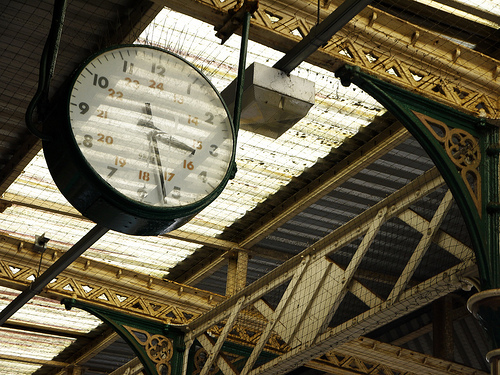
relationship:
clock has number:
[40, 37, 249, 236] [152, 55, 169, 73]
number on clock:
[152, 55, 169, 73] [92, 64, 209, 196]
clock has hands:
[92, 64, 209, 196] [147, 134, 186, 160]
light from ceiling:
[197, 34, 239, 54] [62, 23, 117, 68]